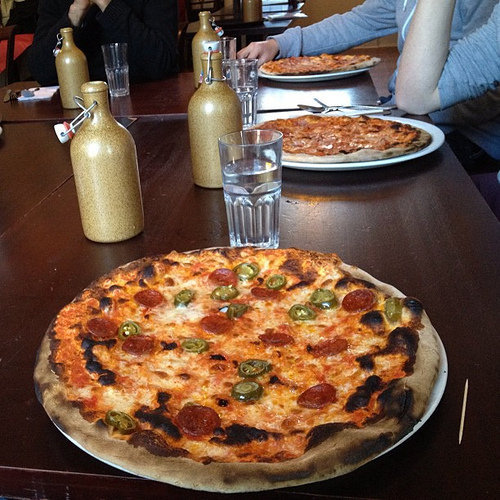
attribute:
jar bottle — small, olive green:
[196, 32, 234, 159]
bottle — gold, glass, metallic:
[53, 81, 143, 243]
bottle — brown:
[74, 66, 146, 242]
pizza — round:
[35, 246, 439, 491]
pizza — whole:
[244, 113, 433, 162]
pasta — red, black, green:
[41, 234, 485, 498]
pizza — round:
[27, 220, 452, 494]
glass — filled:
[217, 128, 288, 248]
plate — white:
[261, 130, 449, 187]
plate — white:
[272, 156, 432, 191]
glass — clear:
[212, 121, 287, 251]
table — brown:
[1, 57, 498, 497]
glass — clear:
[228, 59, 257, 129]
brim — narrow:
[60, 28, 74, 36]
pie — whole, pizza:
[35, 245, 441, 491]